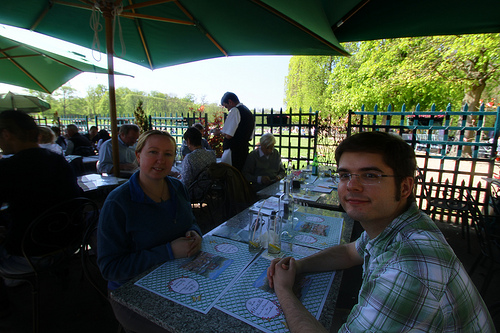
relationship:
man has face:
[334, 134, 496, 331] [335, 155, 398, 216]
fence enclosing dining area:
[37, 105, 487, 220] [21, 117, 333, 319]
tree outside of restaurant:
[276, 39, 343, 134] [9, 5, 489, 314]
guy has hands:
[267, 132, 496, 332] [266, 252, 298, 294]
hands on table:
[170, 225, 202, 264] [252, 180, 337, 329]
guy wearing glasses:
[267, 132, 496, 332] [332, 167, 405, 182]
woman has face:
[99, 126, 208, 286] [139, 132, 176, 178]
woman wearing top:
[93, 126, 208, 333] [92, 175, 205, 279]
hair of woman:
[126, 126, 184, 148] [86, 122, 216, 303]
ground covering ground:
[195, 72, 255, 121] [0, 0, 500, 333]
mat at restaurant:
[156, 220, 254, 324] [7, 20, 496, 187]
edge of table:
[103, 287, 158, 330] [133, 167, 387, 316]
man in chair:
[2, 97, 108, 314] [18, 192, 106, 327]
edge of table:
[103, 287, 264, 333] [223, 156, 350, 331]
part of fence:
[436, 116, 485, 181] [57, 111, 498, 228]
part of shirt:
[389, 257, 445, 305] [331, 199, 495, 331]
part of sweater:
[390, 253, 463, 302] [105, 190, 154, 269]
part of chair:
[77, 252, 102, 287] [30, 198, 112, 315]